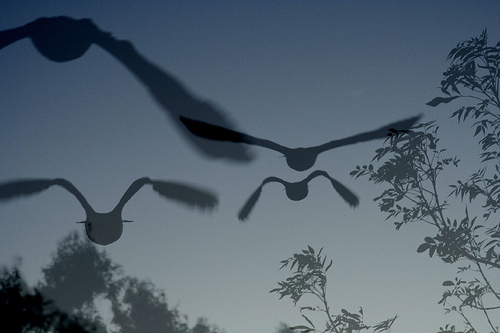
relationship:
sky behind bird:
[0, 1, 499, 331] [242, 164, 354, 220]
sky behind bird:
[0, 1, 499, 331] [210, 113, 391, 184]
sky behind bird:
[0, 1, 499, 331] [30, 159, 183, 266]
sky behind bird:
[0, 1, 499, 331] [22, 8, 129, 98]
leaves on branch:
[367, 160, 498, 258] [421, 206, 498, 272]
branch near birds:
[269, 241, 398, 331] [7, 8, 400, 247]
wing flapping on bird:
[178, 115, 286, 157] [177, 112, 428, 171]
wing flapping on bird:
[318, 112, 427, 152] [177, 112, 428, 171]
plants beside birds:
[270, 23, 498, 332] [7, 8, 400, 247]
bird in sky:
[177, 112, 428, 171] [0, 1, 499, 331]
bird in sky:
[233, 164, 359, 223] [0, 1, 499, 331]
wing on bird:
[318, 110, 421, 158] [177, 112, 428, 171]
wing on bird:
[178, 115, 286, 157] [177, 112, 428, 171]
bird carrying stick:
[0, 175, 220, 245] [74, 216, 131, 227]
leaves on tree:
[348, 26, 497, 333] [350, 27, 497, 329]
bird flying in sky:
[2, 12, 259, 162] [0, 1, 499, 331]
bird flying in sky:
[177, 112, 428, 171] [0, 1, 499, 331]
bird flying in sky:
[0, 175, 220, 245] [0, 1, 499, 331]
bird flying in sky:
[233, 164, 359, 223] [0, 1, 499, 331]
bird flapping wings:
[2, 12, 259, 162] [0, 24, 260, 164]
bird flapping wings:
[177, 112, 428, 171] [179, 111, 422, 151]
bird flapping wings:
[0, 175, 220, 245] [0, 173, 220, 213]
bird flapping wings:
[233, 164, 359, 223] [238, 170, 362, 220]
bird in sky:
[0, 175, 220, 245] [0, 1, 499, 331]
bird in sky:
[2, 12, 259, 162] [0, 1, 499, 331]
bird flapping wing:
[2, 12, 259, 162] [93, 23, 255, 163]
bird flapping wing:
[177, 112, 428, 171] [178, 115, 286, 157]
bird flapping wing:
[177, 112, 428, 171] [318, 112, 427, 152]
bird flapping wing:
[233, 164, 359, 223] [309, 168, 355, 204]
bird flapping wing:
[233, 164, 359, 223] [236, 175, 284, 220]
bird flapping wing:
[0, 175, 220, 245] [122, 175, 219, 213]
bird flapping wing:
[0, 175, 220, 245] [0, 172, 88, 211]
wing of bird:
[1, 177, 92, 213] [0, 175, 220, 245]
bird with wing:
[0, 175, 220, 245] [310, 109, 423, 154]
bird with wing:
[233, 164, 359, 223] [309, 168, 355, 204]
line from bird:
[122, 217, 135, 224] [177, 112, 428, 171]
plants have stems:
[270, 21, 500, 333] [417, 175, 452, 230]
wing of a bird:
[122, 174, 221, 216] [52, 167, 152, 272]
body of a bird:
[284, 180, 308, 202] [233, 164, 359, 223]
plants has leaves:
[270, 21, 500, 333] [366, 120, 490, 281]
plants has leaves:
[270, 21, 500, 333] [346, 37, 498, 332]